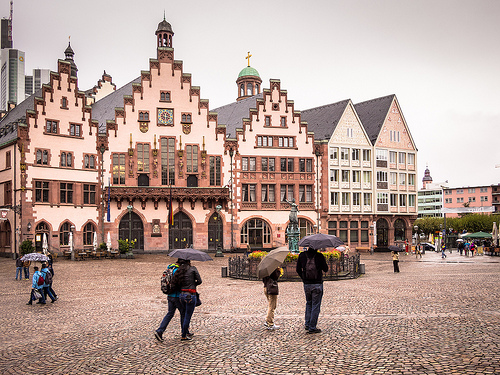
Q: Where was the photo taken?
A: It was taken at the street.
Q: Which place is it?
A: It is a street.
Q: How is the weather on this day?
A: It is cloudy.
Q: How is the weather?
A: It is cloudy.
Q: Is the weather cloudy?
A: Yes, it is cloudy.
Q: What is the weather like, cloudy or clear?
A: It is cloudy.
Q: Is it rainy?
A: No, it is cloudy.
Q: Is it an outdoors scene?
A: Yes, it is outdoors.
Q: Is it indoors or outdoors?
A: It is outdoors.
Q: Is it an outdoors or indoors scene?
A: It is outdoors.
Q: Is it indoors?
A: No, it is outdoors.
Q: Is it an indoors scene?
A: No, it is outdoors.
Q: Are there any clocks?
A: No, there are no clocks.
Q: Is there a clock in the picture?
A: No, there are no clocks.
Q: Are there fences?
A: Yes, there is a fence.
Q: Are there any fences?
A: Yes, there is a fence.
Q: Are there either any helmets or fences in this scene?
A: Yes, there is a fence.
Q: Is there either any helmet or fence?
A: Yes, there is a fence.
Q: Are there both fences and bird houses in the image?
A: No, there is a fence but no bird houses.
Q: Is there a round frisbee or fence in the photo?
A: Yes, there is a round fence.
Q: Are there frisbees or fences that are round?
A: Yes, the fence is round.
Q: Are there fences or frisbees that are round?
A: Yes, the fence is round.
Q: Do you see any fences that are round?
A: Yes, there is a round fence.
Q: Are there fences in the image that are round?
A: Yes, there is a fence that is round.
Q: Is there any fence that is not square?
A: Yes, there is a round fence.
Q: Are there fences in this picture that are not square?
A: Yes, there is a round fence.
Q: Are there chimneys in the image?
A: No, there are no chimneys.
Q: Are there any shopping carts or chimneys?
A: No, there are no chimneys or shopping carts.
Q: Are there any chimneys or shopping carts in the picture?
A: No, there are no chimneys or shopping carts.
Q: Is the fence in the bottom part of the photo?
A: Yes, the fence is in the bottom of the image.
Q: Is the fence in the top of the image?
A: No, the fence is in the bottom of the image.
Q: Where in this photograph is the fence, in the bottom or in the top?
A: The fence is in the bottom of the image.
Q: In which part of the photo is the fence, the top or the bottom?
A: The fence is in the bottom of the image.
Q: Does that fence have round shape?
A: Yes, the fence is round.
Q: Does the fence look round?
A: Yes, the fence is round.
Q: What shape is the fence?
A: The fence is round.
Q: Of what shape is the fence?
A: The fence is round.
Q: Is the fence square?
A: No, the fence is round.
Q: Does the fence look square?
A: No, the fence is round.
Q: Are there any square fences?
A: No, there is a fence but it is round.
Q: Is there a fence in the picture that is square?
A: No, there is a fence but it is round.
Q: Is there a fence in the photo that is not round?
A: No, there is a fence but it is round.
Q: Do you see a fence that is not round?
A: No, there is a fence but it is round.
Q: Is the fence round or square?
A: The fence is round.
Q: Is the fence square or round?
A: The fence is round.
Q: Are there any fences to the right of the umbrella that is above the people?
A: Yes, there is a fence to the right of the umbrella.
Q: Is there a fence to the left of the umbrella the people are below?
A: No, the fence is to the right of the umbrella.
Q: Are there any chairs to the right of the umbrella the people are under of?
A: No, there is a fence to the right of the umbrella.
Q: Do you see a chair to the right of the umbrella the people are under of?
A: No, there is a fence to the right of the umbrella.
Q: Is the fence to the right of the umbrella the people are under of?
A: Yes, the fence is to the right of the umbrella.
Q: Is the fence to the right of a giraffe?
A: No, the fence is to the right of the umbrella.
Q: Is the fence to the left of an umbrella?
A: No, the fence is to the right of an umbrella.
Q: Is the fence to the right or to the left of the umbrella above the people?
A: The fence is to the right of the umbrella.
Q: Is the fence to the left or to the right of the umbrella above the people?
A: The fence is to the right of the umbrella.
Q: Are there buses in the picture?
A: No, there are no buses.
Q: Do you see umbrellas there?
A: Yes, there is an umbrella.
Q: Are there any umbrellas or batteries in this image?
A: Yes, there is an umbrella.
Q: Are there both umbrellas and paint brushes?
A: No, there is an umbrella but no paint brushes.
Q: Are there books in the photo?
A: No, there are no books.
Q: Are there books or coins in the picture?
A: No, there are no books or coins.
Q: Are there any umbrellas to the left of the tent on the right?
A: Yes, there is an umbrella to the left of the tent.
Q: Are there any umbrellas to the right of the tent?
A: No, the umbrella is to the left of the tent.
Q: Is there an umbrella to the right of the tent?
A: No, the umbrella is to the left of the tent.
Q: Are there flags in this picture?
A: No, there are no flags.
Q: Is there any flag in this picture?
A: No, there are no flags.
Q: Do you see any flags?
A: No, there are no flags.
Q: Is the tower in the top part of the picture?
A: Yes, the tower is in the top of the image.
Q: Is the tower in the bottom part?
A: No, the tower is in the top of the image.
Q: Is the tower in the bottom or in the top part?
A: The tower is in the top of the image.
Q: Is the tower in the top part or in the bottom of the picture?
A: The tower is in the top of the image.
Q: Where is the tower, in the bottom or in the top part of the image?
A: The tower is in the top of the image.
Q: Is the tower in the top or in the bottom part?
A: The tower is in the top of the image.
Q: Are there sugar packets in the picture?
A: No, there are no sugar packets.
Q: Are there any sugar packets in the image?
A: No, there are no sugar packets.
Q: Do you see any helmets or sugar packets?
A: No, there are no sugar packets or helmets.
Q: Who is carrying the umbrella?
A: The couple is carrying the umbrella.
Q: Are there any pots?
A: No, there are no pots.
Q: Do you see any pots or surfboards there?
A: No, there are no pots or surfboards.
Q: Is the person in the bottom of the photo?
A: Yes, the person is in the bottom of the image.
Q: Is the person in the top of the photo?
A: No, the person is in the bottom of the image.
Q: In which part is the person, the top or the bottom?
A: The person is in the bottom of the image.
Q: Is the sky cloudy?
A: Yes, the sky is cloudy.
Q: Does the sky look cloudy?
A: Yes, the sky is cloudy.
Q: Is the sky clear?
A: No, the sky is cloudy.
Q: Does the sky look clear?
A: No, the sky is cloudy.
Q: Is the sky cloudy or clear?
A: The sky is cloudy.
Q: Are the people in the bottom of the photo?
A: Yes, the people are in the bottom of the image.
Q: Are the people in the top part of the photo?
A: No, the people are in the bottom of the image.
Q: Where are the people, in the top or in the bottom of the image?
A: The people are in the bottom of the image.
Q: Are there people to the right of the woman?
A: Yes, there are people to the right of the woman.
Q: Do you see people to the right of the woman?
A: Yes, there are people to the right of the woman.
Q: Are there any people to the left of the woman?
A: No, the people are to the right of the woman.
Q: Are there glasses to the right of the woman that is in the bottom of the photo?
A: No, there are people to the right of the woman.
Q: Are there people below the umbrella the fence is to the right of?
A: Yes, there are people below the umbrella.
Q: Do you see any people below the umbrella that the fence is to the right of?
A: Yes, there are people below the umbrella.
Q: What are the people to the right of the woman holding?
A: The people are holding the umbrella.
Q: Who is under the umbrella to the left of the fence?
A: The people are under the umbrella.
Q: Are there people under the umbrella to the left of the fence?
A: Yes, there are people under the umbrella.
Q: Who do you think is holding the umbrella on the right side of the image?
A: The people are holding the umbrella.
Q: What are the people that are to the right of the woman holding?
A: The people are holding the umbrella.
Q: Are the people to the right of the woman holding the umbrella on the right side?
A: Yes, the people are holding the umbrella.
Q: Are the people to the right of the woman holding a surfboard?
A: No, the people are holding the umbrella.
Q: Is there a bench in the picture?
A: No, there are no benches.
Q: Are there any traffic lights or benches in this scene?
A: No, there are no benches or traffic lights.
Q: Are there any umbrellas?
A: Yes, there is an umbrella.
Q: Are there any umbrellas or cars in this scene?
A: Yes, there is an umbrella.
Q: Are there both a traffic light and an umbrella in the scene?
A: No, there is an umbrella but no traffic lights.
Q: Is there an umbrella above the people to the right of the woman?
A: Yes, there is an umbrella above the people.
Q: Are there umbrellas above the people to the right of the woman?
A: Yes, there is an umbrella above the people.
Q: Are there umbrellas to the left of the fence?
A: Yes, there is an umbrella to the left of the fence.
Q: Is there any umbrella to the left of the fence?
A: Yes, there is an umbrella to the left of the fence.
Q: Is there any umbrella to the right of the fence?
A: No, the umbrella is to the left of the fence.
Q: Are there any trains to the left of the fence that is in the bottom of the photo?
A: No, there is an umbrella to the left of the fence.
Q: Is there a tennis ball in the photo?
A: No, there are no tennis balls.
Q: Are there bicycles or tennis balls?
A: No, there are no tennis balls or bicycles.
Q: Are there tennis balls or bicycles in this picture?
A: No, there are no tennis balls or bicycles.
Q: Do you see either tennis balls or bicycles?
A: No, there are no tennis balls or bicycles.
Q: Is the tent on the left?
A: No, the tent is on the right of the image.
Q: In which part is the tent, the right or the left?
A: The tent is on the right of the image.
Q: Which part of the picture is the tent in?
A: The tent is on the right of the image.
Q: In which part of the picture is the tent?
A: The tent is on the right of the image.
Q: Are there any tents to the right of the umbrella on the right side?
A: Yes, there is a tent to the right of the umbrella.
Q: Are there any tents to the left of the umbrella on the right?
A: No, the tent is to the right of the umbrella.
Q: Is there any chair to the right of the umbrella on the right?
A: No, there is a tent to the right of the umbrella.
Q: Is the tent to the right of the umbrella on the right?
A: Yes, the tent is to the right of the umbrella.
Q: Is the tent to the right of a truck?
A: No, the tent is to the right of the umbrella.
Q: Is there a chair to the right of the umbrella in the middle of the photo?
A: No, there is a tent to the right of the umbrella.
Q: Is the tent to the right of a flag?
A: No, the tent is to the right of the umbrella.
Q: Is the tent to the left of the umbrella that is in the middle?
A: No, the tent is to the right of the umbrella.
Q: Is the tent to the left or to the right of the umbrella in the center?
A: The tent is to the right of the umbrella.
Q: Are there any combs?
A: No, there are no combs.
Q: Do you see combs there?
A: No, there are no combs.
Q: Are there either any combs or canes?
A: No, there are no combs or canes.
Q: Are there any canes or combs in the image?
A: No, there are no combs or canes.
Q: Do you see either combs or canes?
A: No, there are no combs or canes.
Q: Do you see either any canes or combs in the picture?
A: No, there are no combs or canes.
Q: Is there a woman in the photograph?
A: Yes, there is a woman.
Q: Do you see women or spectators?
A: Yes, there is a woman.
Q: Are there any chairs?
A: No, there are no chairs.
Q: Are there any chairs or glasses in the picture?
A: No, there are no chairs or glasses.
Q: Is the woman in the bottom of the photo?
A: Yes, the woman is in the bottom of the image.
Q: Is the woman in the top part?
A: No, the woman is in the bottom of the image.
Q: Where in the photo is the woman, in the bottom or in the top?
A: The woman is in the bottom of the image.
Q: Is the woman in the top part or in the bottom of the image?
A: The woman is in the bottom of the image.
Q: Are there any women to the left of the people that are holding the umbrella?
A: Yes, there is a woman to the left of the people.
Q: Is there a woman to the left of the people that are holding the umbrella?
A: Yes, there is a woman to the left of the people.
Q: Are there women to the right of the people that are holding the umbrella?
A: No, the woman is to the left of the people.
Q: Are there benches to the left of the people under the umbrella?
A: No, there is a woman to the left of the people.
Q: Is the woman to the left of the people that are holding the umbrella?
A: Yes, the woman is to the left of the people.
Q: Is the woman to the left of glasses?
A: No, the woman is to the left of the people.